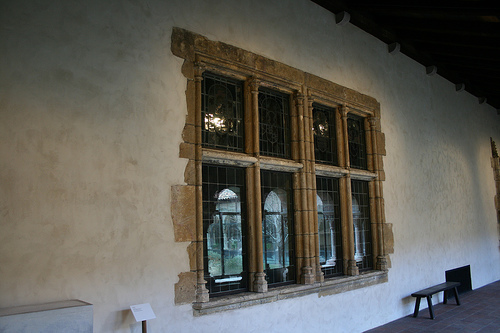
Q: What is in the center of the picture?
A: Window.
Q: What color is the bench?
A: Black.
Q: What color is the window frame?
A: Brown.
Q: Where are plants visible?
A: In the reflection.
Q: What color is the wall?
A: White.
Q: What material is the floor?
A: Brick.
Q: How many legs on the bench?
A: 4.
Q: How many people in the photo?
A: Zero.